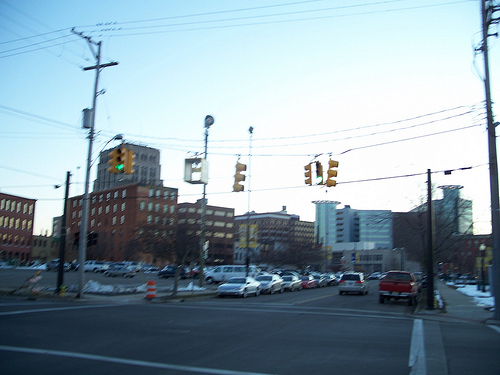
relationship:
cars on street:
[215, 267, 333, 302] [144, 309, 362, 356]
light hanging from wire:
[323, 158, 341, 188] [91, 120, 486, 163]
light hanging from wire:
[315, 159, 322, 194] [91, 120, 486, 163]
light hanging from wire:
[299, 163, 316, 189] [91, 120, 486, 163]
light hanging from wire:
[230, 158, 248, 195] [91, 120, 486, 163]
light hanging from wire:
[118, 147, 139, 177] [91, 120, 486, 163]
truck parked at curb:
[375, 266, 417, 308] [416, 274, 430, 312]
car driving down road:
[335, 270, 368, 297] [280, 302, 388, 347]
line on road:
[168, 294, 424, 313] [44, 239, 461, 372]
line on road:
[139, 299, 413, 319] [44, 239, 461, 372]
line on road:
[3, 341, 231, 374] [44, 239, 461, 372]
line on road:
[403, 313, 423, 371] [44, 239, 461, 372]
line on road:
[0, 299, 126, 316] [44, 239, 461, 372]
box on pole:
[80, 104, 95, 132] [74, 26, 108, 297]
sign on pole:
[228, 219, 278, 260] [245, 220, 249, 281]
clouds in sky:
[12, 98, 80, 155] [1, 2, 498, 248]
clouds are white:
[12, 98, 80, 155] [6, 114, 63, 147]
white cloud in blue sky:
[218, 83, 420, 113] [155, 33, 389, 63]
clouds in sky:
[225, 44, 387, 136] [238, 77, 313, 152]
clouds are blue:
[225, 44, 387, 136] [236, 52, 270, 103]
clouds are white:
[225, 44, 387, 136] [237, 72, 291, 124]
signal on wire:
[207, 154, 259, 194] [175, 130, 264, 165]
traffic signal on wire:
[228, 152, 251, 195] [0, 119, 486, 144]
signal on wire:
[326, 155, 339, 189] [0, 101, 490, 164]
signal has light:
[326, 155, 339, 189] [300, 162, 314, 191]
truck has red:
[379, 270, 424, 307] [374, 263, 414, 297]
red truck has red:
[377, 271, 422, 303] [377, 270, 414, 298]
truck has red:
[336, 251, 448, 311] [377, 270, 414, 298]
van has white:
[206, 262, 258, 284] [207, 258, 255, 281]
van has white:
[213, 266, 278, 284] [202, 263, 260, 280]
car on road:
[335, 270, 375, 297] [2, 277, 499, 372]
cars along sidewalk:
[204, 262, 372, 303] [16, 266, 227, 321]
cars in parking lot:
[98, 262, 137, 277] [0, 261, 315, 298]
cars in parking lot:
[83, 257, 110, 271] [0, 261, 315, 298]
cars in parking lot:
[158, 262, 187, 279] [0, 261, 315, 298]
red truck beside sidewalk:
[377, 271, 420, 303] [396, 291, 424, 370]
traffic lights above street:
[107, 147, 338, 192] [0, 280, 423, 372]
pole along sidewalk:
[70, 25, 118, 300] [0, 277, 493, 324]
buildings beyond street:
[50, 138, 330, 275] [0, 273, 492, 370]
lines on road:
[173, 295, 499, 328] [1, 268, 499, 374]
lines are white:
[173, 295, 499, 328] [169, 285, 399, 318]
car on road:
[217, 275, 257, 297] [2, 276, 424, 372]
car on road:
[257, 271, 282, 294] [2, 276, 424, 372]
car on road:
[280, 273, 297, 290] [2, 276, 424, 372]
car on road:
[299, 271, 313, 291] [2, 276, 424, 372]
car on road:
[316, 271, 330, 286] [2, 276, 424, 372]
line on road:
[237, 300, 392, 317] [160, 311, 322, 368]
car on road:
[335, 270, 368, 297] [181, 305, 378, 369]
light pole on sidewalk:
[195, 110, 216, 290] [166, 273, 216, 297]